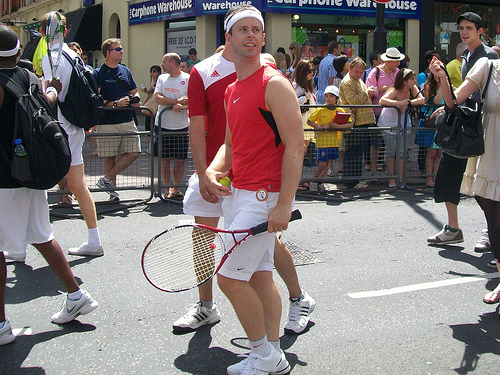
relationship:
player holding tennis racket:
[204, 6, 307, 374] [142, 209, 303, 294]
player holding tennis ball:
[204, 6, 307, 374] [218, 176, 232, 189]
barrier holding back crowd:
[297, 102, 445, 188] [260, 47, 465, 192]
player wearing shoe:
[204, 6, 307, 374] [239, 344, 287, 374]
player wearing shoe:
[204, 6, 307, 374] [227, 354, 247, 374]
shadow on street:
[172, 323, 245, 374] [0, 180, 499, 374]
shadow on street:
[448, 303, 499, 374] [0, 180, 499, 374]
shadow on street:
[0, 320, 97, 373] [0, 180, 499, 374]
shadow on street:
[6, 258, 66, 302] [0, 180, 499, 374]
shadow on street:
[427, 243, 497, 273] [0, 180, 499, 374]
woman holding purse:
[429, 55, 499, 305] [433, 60, 493, 157]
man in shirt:
[366, 47, 416, 181] [364, 65, 405, 116]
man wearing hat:
[366, 47, 416, 181] [380, 46, 404, 63]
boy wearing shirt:
[307, 85, 354, 191] [307, 103, 352, 146]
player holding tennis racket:
[1, 23, 100, 345] [47, 10, 67, 81]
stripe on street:
[346, 271, 500, 299] [0, 180, 499, 374]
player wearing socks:
[204, 6, 307, 374] [246, 335, 282, 356]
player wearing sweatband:
[204, 6, 307, 374] [222, 9, 264, 34]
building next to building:
[101, 1, 419, 124] [0, 0, 101, 69]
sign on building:
[128, 2, 418, 25] [101, 1, 419, 124]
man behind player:
[172, 32, 317, 334] [204, 6, 307, 374]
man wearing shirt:
[172, 32, 317, 334] [189, 51, 239, 168]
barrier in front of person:
[297, 102, 445, 188] [338, 57, 381, 185]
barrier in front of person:
[297, 102, 445, 188] [377, 69, 426, 188]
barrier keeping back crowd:
[297, 102, 445, 188] [260, 47, 465, 192]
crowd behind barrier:
[260, 47, 465, 192] [297, 102, 445, 188]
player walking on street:
[1, 23, 100, 345] [0, 180, 499, 374]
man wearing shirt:
[366, 47, 416, 181] [364, 65, 405, 116]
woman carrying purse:
[429, 55, 499, 305] [433, 60, 493, 157]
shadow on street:
[142, 195, 183, 218] [0, 180, 499, 374]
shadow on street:
[96, 198, 143, 220] [0, 180, 499, 374]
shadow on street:
[68, 255, 98, 266] [0, 180, 499, 374]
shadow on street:
[49, 206, 84, 224] [0, 180, 499, 374]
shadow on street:
[383, 186, 443, 231] [0, 180, 499, 374]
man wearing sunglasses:
[89, 37, 147, 205] [106, 46, 123, 51]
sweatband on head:
[222, 9, 264, 34] [223, 6, 266, 59]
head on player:
[223, 6, 266, 59] [204, 6, 307, 374]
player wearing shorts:
[204, 6, 307, 374] [219, 186, 288, 282]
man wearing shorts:
[172, 32, 317, 334] [181, 173, 222, 218]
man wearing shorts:
[37, 11, 106, 257] [64, 127, 86, 166]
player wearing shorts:
[1, 23, 100, 345] [1, 188, 56, 261]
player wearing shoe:
[1, 23, 100, 345] [2, 321, 15, 347]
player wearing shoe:
[1, 23, 100, 345] [49, 292, 98, 323]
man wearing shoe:
[37, 11, 106, 257] [68, 241, 104, 258]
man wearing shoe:
[172, 32, 317, 334] [171, 304, 222, 330]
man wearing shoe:
[172, 32, 317, 334] [284, 292, 316, 333]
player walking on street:
[204, 6, 307, 374] [0, 180, 499, 374]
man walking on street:
[37, 11, 106, 257] [0, 180, 499, 374]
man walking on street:
[172, 32, 317, 334] [0, 180, 499, 374]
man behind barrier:
[89, 37, 147, 205] [84, 102, 194, 208]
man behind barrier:
[155, 52, 190, 201] [84, 102, 194, 208]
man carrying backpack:
[37, 11, 106, 257] [51, 47, 104, 129]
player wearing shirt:
[204, 6, 307, 374] [226, 65, 288, 192]